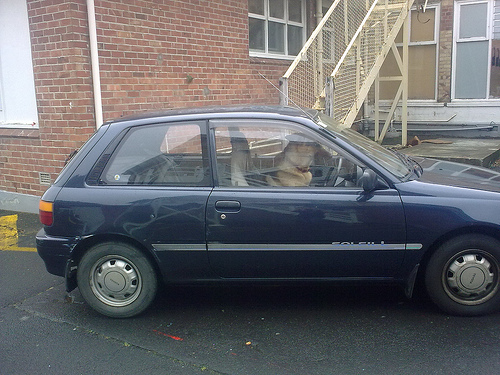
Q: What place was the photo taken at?
A: It was taken at the street.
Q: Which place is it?
A: It is a street.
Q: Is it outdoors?
A: Yes, it is outdoors.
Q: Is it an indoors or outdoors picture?
A: It is outdoors.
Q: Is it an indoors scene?
A: No, it is outdoors.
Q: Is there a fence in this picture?
A: No, there are no fences.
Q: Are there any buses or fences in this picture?
A: No, there are no fences or buses.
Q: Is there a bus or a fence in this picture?
A: No, there are no fences or buses.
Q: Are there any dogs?
A: Yes, there is a dog.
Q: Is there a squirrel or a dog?
A: Yes, there is a dog.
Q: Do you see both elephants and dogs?
A: No, there is a dog but no elephants.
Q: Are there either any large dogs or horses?
A: Yes, there is a large dog.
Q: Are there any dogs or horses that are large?
A: Yes, the dog is large.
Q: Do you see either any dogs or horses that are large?
A: Yes, the dog is large.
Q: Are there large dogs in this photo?
A: Yes, there is a large dog.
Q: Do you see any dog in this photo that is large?
A: Yes, there is a dog that is large.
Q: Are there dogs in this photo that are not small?
A: Yes, there is a large dog.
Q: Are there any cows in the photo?
A: No, there are no cows.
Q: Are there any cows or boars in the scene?
A: No, there are no cows or boars.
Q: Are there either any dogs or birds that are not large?
A: No, there is a dog but it is large.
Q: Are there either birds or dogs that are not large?
A: No, there is a dog but it is large.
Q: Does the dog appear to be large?
A: Yes, the dog is large.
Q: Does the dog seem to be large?
A: Yes, the dog is large.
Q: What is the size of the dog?
A: The dog is large.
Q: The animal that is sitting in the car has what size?
A: The dog is large.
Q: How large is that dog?
A: The dog is large.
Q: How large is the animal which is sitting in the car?
A: The dog is large.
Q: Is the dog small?
A: No, the dog is large.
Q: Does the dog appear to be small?
A: No, the dog is large.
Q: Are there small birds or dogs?
A: No, there is a dog but it is large.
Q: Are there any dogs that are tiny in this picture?
A: No, there is a dog but it is large.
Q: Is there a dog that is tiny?
A: No, there is a dog but it is large.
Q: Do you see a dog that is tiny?
A: No, there is a dog but it is large.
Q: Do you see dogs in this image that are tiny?
A: No, there is a dog but it is large.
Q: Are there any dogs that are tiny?
A: No, there is a dog but it is large.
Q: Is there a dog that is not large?
A: No, there is a dog but it is large.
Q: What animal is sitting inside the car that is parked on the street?
A: The dog is sitting inside the car.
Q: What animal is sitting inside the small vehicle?
A: The dog is sitting inside the car.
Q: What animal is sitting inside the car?
A: The dog is sitting inside the car.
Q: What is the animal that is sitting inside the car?
A: The animal is a dog.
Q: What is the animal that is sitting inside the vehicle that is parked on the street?
A: The animal is a dog.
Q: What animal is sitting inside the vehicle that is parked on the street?
A: The animal is a dog.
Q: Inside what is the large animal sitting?
A: The dog is sitting inside the car.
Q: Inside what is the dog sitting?
A: The dog is sitting inside the car.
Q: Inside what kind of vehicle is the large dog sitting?
A: The dog is sitting inside the car.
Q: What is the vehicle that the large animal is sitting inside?
A: The vehicle is a car.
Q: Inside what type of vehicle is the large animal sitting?
A: The dog is sitting inside the car.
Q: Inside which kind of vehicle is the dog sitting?
A: The dog is sitting inside the car.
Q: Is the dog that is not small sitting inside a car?
A: Yes, the dog is sitting inside a car.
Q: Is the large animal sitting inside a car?
A: Yes, the dog is sitting inside a car.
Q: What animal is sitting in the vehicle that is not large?
A: The dog is sitting in the car.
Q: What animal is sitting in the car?
A: The dog is sitting in the car.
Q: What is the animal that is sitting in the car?
A: The animal is a dog.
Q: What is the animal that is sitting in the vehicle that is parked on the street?
A: The animal is a dog.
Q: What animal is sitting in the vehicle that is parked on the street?
A: The animal is a dog.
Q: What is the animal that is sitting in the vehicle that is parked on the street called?
A: The animal is a dog.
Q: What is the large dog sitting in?
A: The dog is sitting in the car.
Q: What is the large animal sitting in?
A: The dog is sitting in the car.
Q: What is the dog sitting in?
A: The dog is sitting in the car.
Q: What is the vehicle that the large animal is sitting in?
A: The vehicle is a car.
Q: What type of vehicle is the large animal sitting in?
A: The dog is sitting in the car.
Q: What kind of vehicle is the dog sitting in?
A: The dog is sitting in the car.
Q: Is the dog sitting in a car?
A: Yes, the dog is sitting in a car.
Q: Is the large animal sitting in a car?
A: Yes, the dog is sitting in a car.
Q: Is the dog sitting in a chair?
A: No, the dog is sitting in a car.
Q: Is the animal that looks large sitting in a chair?
A: No, the dog is sitting in a car.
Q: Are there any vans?
A: No, there are no vans.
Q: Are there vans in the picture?
A: No, there are no vans.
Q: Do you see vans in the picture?
A: No, there are no vans.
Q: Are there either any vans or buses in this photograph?
A: No, there are no vans or buses.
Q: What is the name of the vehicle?
A: The vehicle is a car.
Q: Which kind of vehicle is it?
A: The vehicle is a car.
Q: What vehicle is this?
A: This is a car.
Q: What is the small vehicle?
A: The vehicle is a car.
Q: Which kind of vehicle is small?
A: The vehicle is a car.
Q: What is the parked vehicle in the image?
A: The vehicle is a car.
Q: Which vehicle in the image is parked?
A: The vehicle is a car.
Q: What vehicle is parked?
A: The vehicle is a car.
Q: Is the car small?
A: Yes, the car is small.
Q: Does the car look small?
A: Yes, the car is small.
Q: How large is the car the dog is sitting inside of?
A: The car is small.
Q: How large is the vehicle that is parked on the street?
A: The car is small.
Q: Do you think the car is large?
A: No, the car is small.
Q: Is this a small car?
A: Yes, this is a small car.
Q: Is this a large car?
A: No, this is a small car.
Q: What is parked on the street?
A: The car is parked on the street.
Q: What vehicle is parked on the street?
A: The vehicle is a car.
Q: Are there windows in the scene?
A: Yes, there is a window.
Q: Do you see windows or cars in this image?
A: Yes, there is a window.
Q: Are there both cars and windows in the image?
A: Yes, there are both a window and a car.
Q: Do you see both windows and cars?
A: Yes, there are both a window and a car.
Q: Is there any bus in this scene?
A: No, there are no buses.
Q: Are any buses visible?
A: No, there are no buses.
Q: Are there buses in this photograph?
A: No, there are no buses.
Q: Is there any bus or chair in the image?
A: No, there are no buses or chairs.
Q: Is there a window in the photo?
A: Yes, there is a window.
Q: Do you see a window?
A: Yes, there is a window.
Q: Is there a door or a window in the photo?
A: Yes, there is a window.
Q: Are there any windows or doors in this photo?
A: Yes, there is a window.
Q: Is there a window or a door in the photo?
A: Yes, there is a window.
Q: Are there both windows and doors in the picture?
A: Yes, there are both a window and a door.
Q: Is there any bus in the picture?
A: No, there are no buses.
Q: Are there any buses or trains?
A: No, there are no buses or trains.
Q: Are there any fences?
A: No, there are no fences.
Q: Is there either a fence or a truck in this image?
A: No, there are no fences or trucks.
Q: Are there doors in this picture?
A: Yes, there is a door.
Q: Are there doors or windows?
A: Yes, there is a door.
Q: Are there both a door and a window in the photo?
A: Yes, there are both a door and a window.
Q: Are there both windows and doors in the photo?
A: Yes, there are both a door and a window.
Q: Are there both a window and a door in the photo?
A: Yes, there are both a door and a window.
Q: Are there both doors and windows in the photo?
A: Yes, there are both a door and a window.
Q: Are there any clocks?
A: No, there are no clocks.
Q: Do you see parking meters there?
A: No, there are no parking meters.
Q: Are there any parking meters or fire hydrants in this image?
A: No, there are no parking meters or fire hydrants.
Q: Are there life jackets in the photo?
A: No, there are no life jackets.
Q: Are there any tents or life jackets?
A: No, there are no life jackets or tents.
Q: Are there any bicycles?
A: No, there are no bicycles.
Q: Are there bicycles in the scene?
A: No, there are no bicycles.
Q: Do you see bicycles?
A: No, there are no bicycles.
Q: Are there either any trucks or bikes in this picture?
A: No, there are no bikes or trucks.